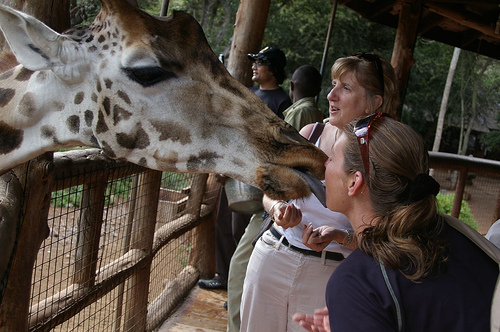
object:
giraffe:
[2, 1, 327, 203]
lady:
[293, 111, 498, 331]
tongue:
[296, 169, 328, 208]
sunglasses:
[354, 112, 388, 187]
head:
[323, 116, 432, 213]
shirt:
[326, 219, 498, 331]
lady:
[238, 50, 395, 331]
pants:
[240, 223, 347, 331]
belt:
[267, 227, 347, 263]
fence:
[2, 147, 223, 332]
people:
[198, 46, 496, 330]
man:
[197, 46, 286, 292]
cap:
[248, 44, 288, 66]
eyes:
[327, 154, 334, 164]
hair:
[345, 116, 450, 287]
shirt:
[245, 89, 294, 126]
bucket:
[223, 178, 266, 213]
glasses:
[257, 61, 264, 65]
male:
[226, 66, 319, 331]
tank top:
[274, 120, 359, 255]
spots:
[110, 120, 156, 153]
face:
[325, 132, 348, 215]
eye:
[120, 62, 177, 89]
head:
[51, 2, 329, 201]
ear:
[1, 3, 67, 74]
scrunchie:
[409, 171, 442, 201]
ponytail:
[356, 183, 451, 284]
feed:
[277, 202, 327, 237]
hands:
[299, 224, 341, 253]